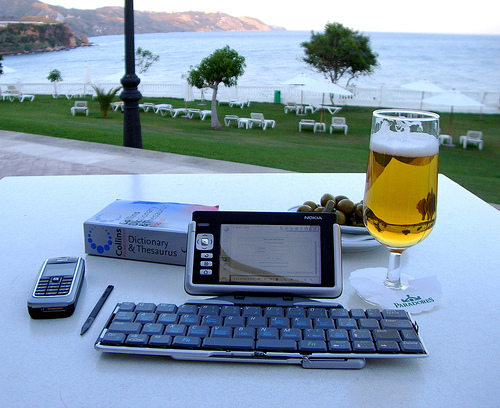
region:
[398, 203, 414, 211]
beer in wine glass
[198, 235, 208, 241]
menu button on pad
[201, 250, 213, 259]
power button on pad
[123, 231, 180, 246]
word dictionary on book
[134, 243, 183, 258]
word thesaurus on book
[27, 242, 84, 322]
black cellphone on table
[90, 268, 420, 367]
keyboard on the table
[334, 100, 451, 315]
glass of beer on table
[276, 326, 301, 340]
key on the keyboard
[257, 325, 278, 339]
key on the keyboard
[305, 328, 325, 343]
key on the keyboard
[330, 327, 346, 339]
key on the keyboard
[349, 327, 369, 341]
key on the keyboard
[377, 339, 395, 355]
key on the keyboard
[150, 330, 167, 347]
key on the keyboard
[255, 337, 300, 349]
key on the keyboard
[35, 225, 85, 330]
a cell phone sitting on table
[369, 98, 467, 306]
a glass of beer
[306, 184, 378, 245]
a bowl with green olives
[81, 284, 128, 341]
a stylus for the tablet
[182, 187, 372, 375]
a tablet connected to a keyboard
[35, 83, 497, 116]
a white metal fence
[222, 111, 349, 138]
tables and chairs for people to sit on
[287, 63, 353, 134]
the white umbrellas to help keep the shade off of people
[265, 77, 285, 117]
a green trash can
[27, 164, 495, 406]
a white table holding different items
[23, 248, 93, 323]
a cell phone on a table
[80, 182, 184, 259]
a book on a table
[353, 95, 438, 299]
a glass of beear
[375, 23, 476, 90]
a large body of water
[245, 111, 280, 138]
a white beach chair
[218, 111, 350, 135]
several white beach chairs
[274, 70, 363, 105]
two white umbrellas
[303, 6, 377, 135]
a green tree by the water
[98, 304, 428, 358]
a small computer keyboard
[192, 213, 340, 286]
a small screen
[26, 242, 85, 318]
a cell phone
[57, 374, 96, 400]
a table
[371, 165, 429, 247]
the liquid in the glass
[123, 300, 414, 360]
the keyboard is black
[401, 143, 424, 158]
small white bubbles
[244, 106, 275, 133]
beach chair down by the water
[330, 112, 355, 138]
beach chair down by the water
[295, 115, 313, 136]
beach chair down by the water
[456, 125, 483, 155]
beach chair down by the water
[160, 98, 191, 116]
beach chair down by the water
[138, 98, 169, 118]
beach chair down by the water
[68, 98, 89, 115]
beach chair down by the water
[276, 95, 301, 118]
beach chair down by the water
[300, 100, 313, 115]
beach chair down by the water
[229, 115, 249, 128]
beach chair down by the water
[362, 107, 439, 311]
glass of champagne on the table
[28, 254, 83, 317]
a small compact cellphone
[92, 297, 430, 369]
a small computer keyboard